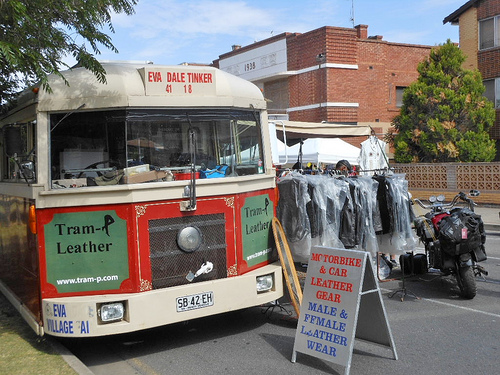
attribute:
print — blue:
[38, 304, 99, 349]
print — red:
[310, 249, 360, 306]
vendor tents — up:
[257, 118, 391, 173]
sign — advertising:
[262, 237, 404, 372]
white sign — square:
[216, 36, 287, 81]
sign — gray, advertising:
[294, 247, 401, 373]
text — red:
[143, 70, 215, 93]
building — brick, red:
[208, 21, 458, 175]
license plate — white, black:
[171, 290, 218, 311]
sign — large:
[44, 210, 129, 292]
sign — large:
[241, 192, 273, 268]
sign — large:
[147, 67, 215, 94]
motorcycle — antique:
[394, 197, 478, 255]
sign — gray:
[298, 303, 351, 361]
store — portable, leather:
[31, 57, 439, 368]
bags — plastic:
[282, 168, 411, 258]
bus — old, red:
[4, 58, 287, 339]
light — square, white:
[255, 269, 277, 294]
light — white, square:
[98, 300, 124, 322]